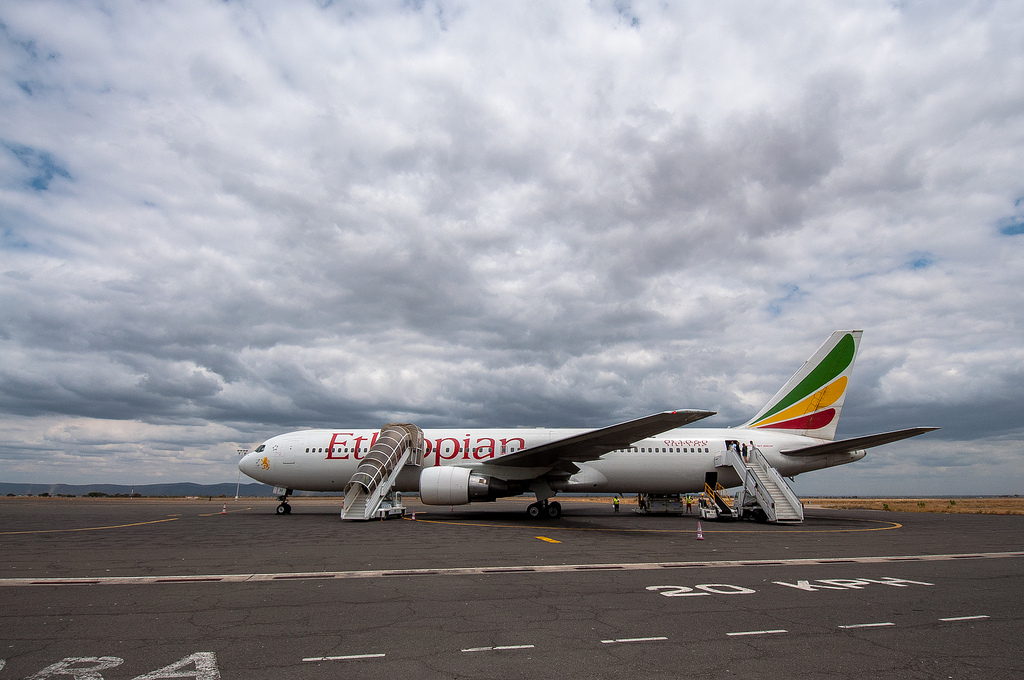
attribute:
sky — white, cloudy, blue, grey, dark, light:
[191, 101, 850, 299]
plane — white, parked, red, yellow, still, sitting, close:
[266, 376, 887, 546]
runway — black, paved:
[242, 511, 772, 651]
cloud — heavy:
[177, 314, 493, 382]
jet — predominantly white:
[143, 357, 854, 459]